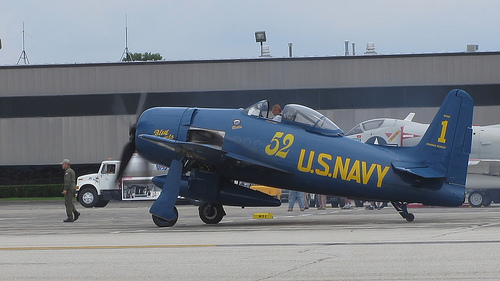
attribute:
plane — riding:
[133, 88, 475, 225]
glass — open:
[269, 92, 337, 127]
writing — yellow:
[248, 125, 420, 211]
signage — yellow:
[297, 140, 389, 189]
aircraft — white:
[115, 87, 475, 226]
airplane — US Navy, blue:
[128, 75, 479, 232]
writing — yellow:
[435, 119, 447, 143]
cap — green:
[58, 156, 70, 165]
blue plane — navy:
[133, 85, 469, 232]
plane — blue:
[114, 78, 476, 231]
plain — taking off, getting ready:
[116, 81, 481, 231]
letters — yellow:
[293, 141, 395, 192]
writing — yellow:
[262, 129, 387, 192]